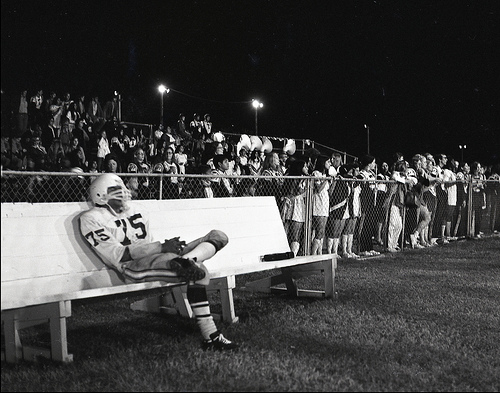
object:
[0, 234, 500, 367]
grass lawn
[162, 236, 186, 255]
hands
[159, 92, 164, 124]
light poles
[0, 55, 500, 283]
sideline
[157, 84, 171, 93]
lights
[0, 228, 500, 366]
ground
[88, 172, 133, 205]
helmet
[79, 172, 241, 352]
football player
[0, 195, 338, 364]
bench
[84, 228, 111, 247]
number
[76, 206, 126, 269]
sleeve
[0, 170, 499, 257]
fence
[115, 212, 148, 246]
number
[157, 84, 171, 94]
light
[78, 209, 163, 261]
arm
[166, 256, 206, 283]
shoe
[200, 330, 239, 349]
shoe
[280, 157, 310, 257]
girl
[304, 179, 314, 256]
post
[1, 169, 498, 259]
stands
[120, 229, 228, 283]
pants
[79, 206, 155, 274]
jersey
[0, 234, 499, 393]
football field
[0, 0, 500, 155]
background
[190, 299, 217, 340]
sock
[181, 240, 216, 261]
sock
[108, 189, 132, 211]
faceguard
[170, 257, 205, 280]
cleat